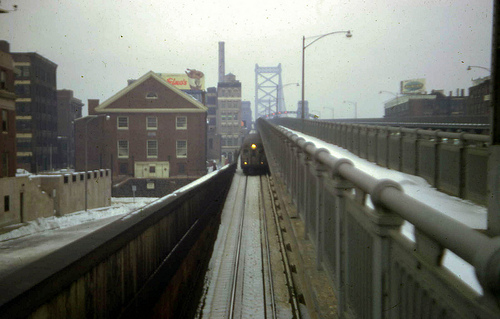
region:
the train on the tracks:
[237, 133, 270, 173]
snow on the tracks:
[245, 176, 263, 213]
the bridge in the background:
[248, 61, 294, 125]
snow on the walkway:
[293, 123, 358, 172]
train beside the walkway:
[241, 127, 269, 173]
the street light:
[299, 18, 361, 100]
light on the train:
[246, 140, 263, 157]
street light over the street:
[72, 99, 119, 184]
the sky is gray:
[28, 11, 490, 78]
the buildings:
[5, 54, 219, 161]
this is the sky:
[363, 2, 460, 62]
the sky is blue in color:
[416, 4, 456, 38]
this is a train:
[238, 130, 278, 180]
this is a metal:
[259, 202, 276, 249]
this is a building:
[122, 76, 204, 168]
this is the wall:
[154, 114, 176, 145]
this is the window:
[145, 113, 157, 127]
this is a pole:
[303, 35, 311, 108]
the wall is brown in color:
[65, 177, 80, 199]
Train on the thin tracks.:
[239, 129, 268, 177]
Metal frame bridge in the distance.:
[253, 64, 285, 119]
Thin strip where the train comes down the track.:
[196, 164, 315, 316]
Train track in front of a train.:
[227, 172, 269, 317]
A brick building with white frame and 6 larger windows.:
[94, 72, 207, 181]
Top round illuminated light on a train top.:
[250, 142, 256, 150]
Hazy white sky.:
[3, 0, 491, 120]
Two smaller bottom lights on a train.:
[243, 159, 264, 165]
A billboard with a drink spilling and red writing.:
[154, 67, 208, 91]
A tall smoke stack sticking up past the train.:
[217, 38, 227, 83]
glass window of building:
[115, 115, 129, 130]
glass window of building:
[145, 113, 157, 128]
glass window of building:
[175, 115, 187, 129]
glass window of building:
[116, 138, 128, 154]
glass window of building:
[146, 140, 158, 155]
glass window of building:
[174, 138, 188, 158]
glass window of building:
[144, 92, 160, 99]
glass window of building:
[206, 95, 216, 103]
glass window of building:
[206, 105, 216, 117]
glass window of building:
[208, 117, 217, 127]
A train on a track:
[239, 134, 270, 173]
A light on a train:
[247, 141, 258, 148]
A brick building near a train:
[97, 73, 204, 173]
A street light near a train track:
[297, 30, 355, 125]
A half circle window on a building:
[142, 90, 157, 100]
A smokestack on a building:
[216, 42, 225, 79]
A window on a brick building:
[173, 113, 191, 133]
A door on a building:
[136, 160, 168, 175]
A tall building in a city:
[17, 48, 60, 171]